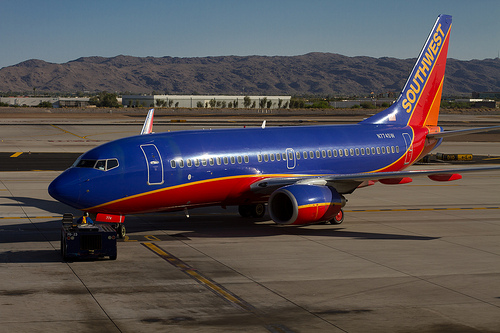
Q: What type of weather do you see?
A: It is clear.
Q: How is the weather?
A: It is clear.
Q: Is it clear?
A: Yes, it is clear.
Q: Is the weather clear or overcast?
A: It is clear.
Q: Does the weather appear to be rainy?
A: No, it is clear.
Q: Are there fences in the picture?
A: No, there are no fences.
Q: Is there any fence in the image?
A: No, there are no fences.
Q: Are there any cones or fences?
A: No, there are no fences or cones.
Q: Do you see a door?
A: Yes, there is a door.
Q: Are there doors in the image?
A: Yes, there is a door.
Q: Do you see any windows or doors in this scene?
A: Yes, there is a door.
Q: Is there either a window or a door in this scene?
A: Yes, there is a door.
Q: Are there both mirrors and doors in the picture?
A: No, there is a door but no mirrors.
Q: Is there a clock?
A: No, there are no clocks.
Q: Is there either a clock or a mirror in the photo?
A: No, there are no clocks or mirrors.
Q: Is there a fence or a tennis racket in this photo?
A: No, there are no fences or rackets.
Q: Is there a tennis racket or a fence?
A: No, there are no fences or rackets.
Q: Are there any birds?
A: No, there are no birds.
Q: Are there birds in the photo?
A: No, there are no birds.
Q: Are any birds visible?
A: No, there are no birds.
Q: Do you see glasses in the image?
A: No, there are no glasses.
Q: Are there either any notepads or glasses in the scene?
A: No, there are no glasses or notepads.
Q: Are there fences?
A: No, there are no fences.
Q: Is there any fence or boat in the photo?
A: No, there are no fences or boats.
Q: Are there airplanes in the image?
A: Yes, there is an airplane.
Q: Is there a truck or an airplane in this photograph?
A: Yes, there is an airplane.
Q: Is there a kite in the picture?
A: No, there are no kites.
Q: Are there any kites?
A: No, there are no kites.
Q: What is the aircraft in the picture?
A: The aircraft is an airplane.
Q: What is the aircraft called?
A: The aircraft is an airplane.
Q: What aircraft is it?
A: The aircraft is an airplane.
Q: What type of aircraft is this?
A: This is an airplane.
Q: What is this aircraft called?
A: This is an airplane.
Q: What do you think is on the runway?
A: The airplane is on the runway.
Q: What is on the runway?
A: The airplane is on the runway.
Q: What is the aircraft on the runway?
A: The aircraft is an airplane.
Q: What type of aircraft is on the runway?
A: The aircraft is an airplane.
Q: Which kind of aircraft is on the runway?
A: The aircraft is an airplane.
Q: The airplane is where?
A: The airplane is on the runway.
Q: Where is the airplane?
A: The airplane is on the runway.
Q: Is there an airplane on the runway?
A: Yes, there is an airplane on the runway.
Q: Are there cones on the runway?
A: No, there is an airplane on the runway.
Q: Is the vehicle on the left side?
A: Yes, the vehicle is on the left of the image.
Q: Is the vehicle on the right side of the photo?
A: No, the vehicle is on the left of the image.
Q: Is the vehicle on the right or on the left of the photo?
A: The vehicle is on the left of the image.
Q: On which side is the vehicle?
A: The vehicle is on the left of the image.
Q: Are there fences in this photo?
A: No, there are no fences.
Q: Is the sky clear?
A: Yes, the sky is clear.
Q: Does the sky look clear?
A: Yes, the sky is clear.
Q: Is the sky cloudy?
A: No, the sky is clear.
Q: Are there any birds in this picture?
A: No, there are no birds.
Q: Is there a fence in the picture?
A: No, there are no fences.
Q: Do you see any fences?
A: No, there are no fences.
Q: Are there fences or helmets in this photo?
A: No, there are no fences or helmets.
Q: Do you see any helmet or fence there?
A: No, there are no fences or helmets.